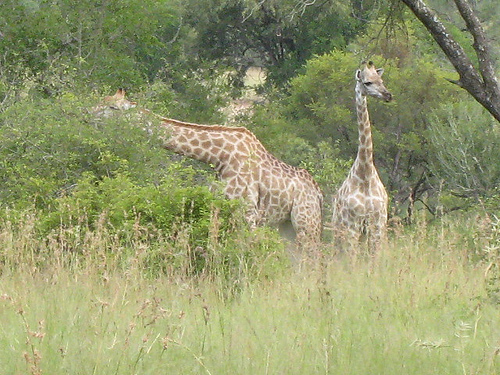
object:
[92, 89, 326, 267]
giraffe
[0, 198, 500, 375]
grass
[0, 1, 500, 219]
background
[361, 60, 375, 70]
hairy horns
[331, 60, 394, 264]
giraffe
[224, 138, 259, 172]
brown spots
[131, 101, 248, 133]
mane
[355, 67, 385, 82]
ears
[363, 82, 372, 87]
eyes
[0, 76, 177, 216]
brush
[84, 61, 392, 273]
giraffes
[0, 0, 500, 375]
field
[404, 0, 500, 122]
branches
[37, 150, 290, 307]
bush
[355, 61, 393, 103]
head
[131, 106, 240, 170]
neck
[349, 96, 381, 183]
neck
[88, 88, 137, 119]
head